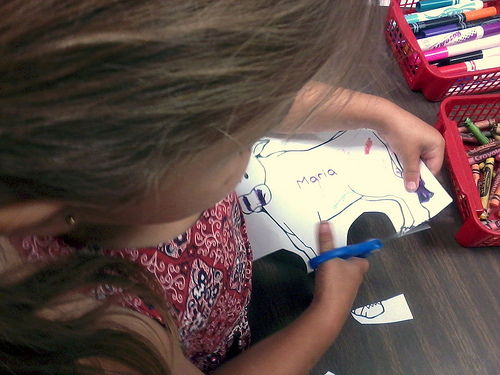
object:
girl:
[3, 0, 445, 374]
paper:
[235, 128, 454, 325]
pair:
[308, 222, 436, 266]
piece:
[351, 294, 415, 327]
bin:
[439, 91, 499, 247]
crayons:
[457, 115, 497, 234]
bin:
[383, 0, 499, 104]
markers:
[402, 2, 499, 73]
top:
[0, 1, 380, 62]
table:
[249, 2, 499, 373]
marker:
[439, 35, 499, 73]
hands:
[308, 111, 444, 302]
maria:
[295, 166, 339, 189]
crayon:
[464, 118, 489, 141]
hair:
[0, 3, 377, 372]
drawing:
[232, 124, 429, 268]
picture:
[4, 2, 499, 374]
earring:
[64, 213, 78, 230]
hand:
[312, 221, 371, 300]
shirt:
[0, 190, 254, 371]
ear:
[42, 217, 74, 234]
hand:
[387, 104, 446, 192]